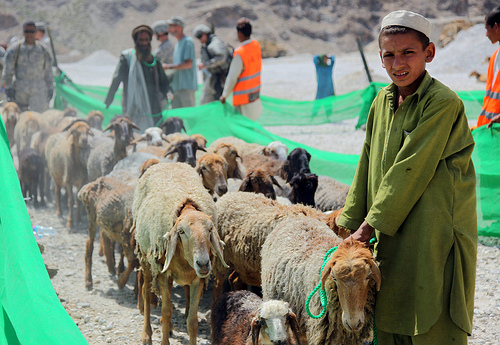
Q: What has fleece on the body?
A: Sheep.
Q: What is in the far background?
A: Mountains.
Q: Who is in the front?
A: Young boy.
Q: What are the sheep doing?
A: Following the herd.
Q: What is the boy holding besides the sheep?
A: Rope.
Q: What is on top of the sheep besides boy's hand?
A: Rope.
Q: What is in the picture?
A: Sheep.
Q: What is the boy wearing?
A: Green robe.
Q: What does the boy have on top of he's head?
A: Hat.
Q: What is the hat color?
A: White.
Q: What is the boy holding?
A: Sheep.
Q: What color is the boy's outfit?
A: Green.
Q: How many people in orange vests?
A: Two.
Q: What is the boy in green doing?
A: Holding a sheep.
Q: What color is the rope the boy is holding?
A: Green.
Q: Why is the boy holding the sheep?
A: So it does not run away.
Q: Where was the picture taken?
A: In a middle eastern village.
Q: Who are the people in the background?
A: Villagers.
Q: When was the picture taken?
A: During daytime.